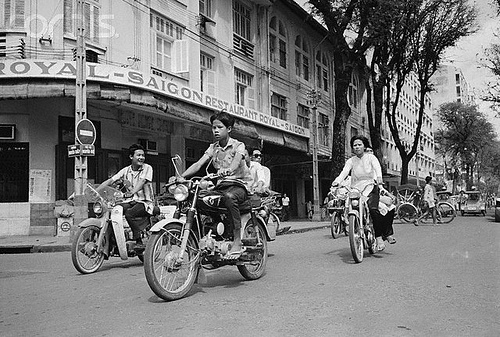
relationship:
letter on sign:
[9, 59, 30, 75] [3, 53, 117, 84]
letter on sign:
[9, 59, 30, 75] [1, 52, 115, 93]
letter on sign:
[57, 60, 75, 78] [2, 49, 110, 85]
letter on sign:
[87, 62, 110, 83] [3, 53, 117, 84]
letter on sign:
[124, 68, 148, 86] [7, 55, 207, 103]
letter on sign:
[144, 73, 160, 89] [4, 51, 196, 107]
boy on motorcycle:
[178, 109, 279, 259] [138, 149, 275, 300]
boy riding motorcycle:
[93, 139, 158, 237] [66, 175, 183, 279]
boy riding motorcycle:
[178, 109, 279, 259] [138, 149, 275, 300]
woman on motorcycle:
[330, 134, 384, 247] [326, 179, 402, 264]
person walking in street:
[422, 174, 440, 224] [1, 216, 496, 335]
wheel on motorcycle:
[140, 221, 203, 301] [138, 149, 275, 300]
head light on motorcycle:
[167, 180, 195, 206] [138, 149, 275, 300]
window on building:
[145, 5, 197, 88] [3, 4, 338, 251]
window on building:
[199, 47, 222, 100] [7, 7, 342, 155]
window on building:
[233, 63, 257, 108] [3, 4, 338, 251]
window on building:
[269, 85, 291, 122] [3, 4, 338, 251]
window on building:
[292, 100, 313, 131] [3, 4, 338, 251]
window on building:
[314, 106, 336, 146] [3, 4, 338, 251]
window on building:
[313, 43, 332, 93] [3, 4, 338, 251]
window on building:
[266, 9, 289, 68] [3, 4, 338, 251]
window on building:
[216, 28, 263, 68] [90, 36, 298, 117]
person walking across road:
[422, 174, 440, 224] [427, 259, 470, 294]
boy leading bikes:
[178, 109, 279, 259] [237, 137, 401, 234]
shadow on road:
[133, 290, 178, 315] [248, 309, 312, 334]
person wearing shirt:
[342, 143, 402, 215] [337, 150, 374, 202]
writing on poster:
[30, 174, 60, 215] [24, 152, 56, 218]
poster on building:
[24, 152, 56, 218] [14, 84, 89, 184]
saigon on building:
[97, 63, 202, 110] [75, 42, 217, 149]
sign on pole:
[61, 117, 112, 165] [57, 55, 104, 234]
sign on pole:
[61, 117, 112, 165] [66, 58, 99, 122]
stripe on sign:
[64, 122, 94, 139] [61, 117, 112, 165]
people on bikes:
[97, 111, 391, 261] [79, 210, 364, 261]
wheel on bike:
[140, 221, 203, 301] [157, 181, 279, 285]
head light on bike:
[167, 180, 195, 206] [166, 204, 282, 288]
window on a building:
[145, 5, 197, 88] [3, 3, 455, 263]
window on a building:
[219, 66, 257, 106] [64, 0, 414, 214]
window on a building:
[269, 85, 291, 122] [50, 9, 418, 237]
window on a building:
[265, 13, 299, 94] [26, 0, 491, 261]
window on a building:
[293, 28, 311, 82] [108, 5, 439, 205]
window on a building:
[313, 43, 332, 93] [156, 2, 370, 206]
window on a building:
[315, 108, 333, 148] [48, 0, 371, 225]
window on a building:
[297, 98, 310, 130] [47, 2, 400, 251]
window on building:
[315, 39, 338, 99] [7, 7, 342, 155]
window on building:
[293, 28, 311, 82] [1, 0, 373, 134]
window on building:
[265, 13, 299, 94] [2, 0, 338, 145]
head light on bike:
[167, 180, 195, 206] [144, 175, 280, 300]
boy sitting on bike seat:
[178, 109, 279, 259] [232, 186, 261, 206]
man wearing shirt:
[102, 146, 158, 211] [99, 164, 155, 196]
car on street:
[459, 195, 493, 213] [392, 250, 490, 313]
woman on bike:
[330, 134, 384, 247] [332, 200, 392, 261]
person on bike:
[176, 107, 264, 262] [132, 150, 272, 303]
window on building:
[199, 47, 222, 100] [3, 3, 455, 263]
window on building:
[292, 100, 313, 131] [9, 4, 401, 312]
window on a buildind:
[145, 5, 197, 88] [133, 37, 251, 84]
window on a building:
[297, 98, 310, 130] [1, 1, 442, 234]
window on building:
[315, 108, 333, 148] [1, 1, 442, 234]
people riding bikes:
[97, 111, 391, 261] [66, 178, 388, 305]